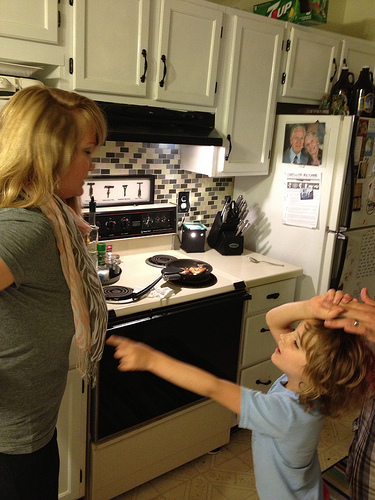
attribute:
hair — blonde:
[1, 85, 108, 212]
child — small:
[104, 319, 371, 500]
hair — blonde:
[298, 316, 374, 421]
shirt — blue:
[233, 372, 331, 499]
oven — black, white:
[74, 202, 252, 499]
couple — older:
[282, 127, 322, 167]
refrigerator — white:
[231, 111, 373, 332]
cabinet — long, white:
[180, 14, 285, 178]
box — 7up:
[250, 0, 331, 31]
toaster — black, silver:
[179, 219, 208, 254]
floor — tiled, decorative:
[107, 406, 361, 499]